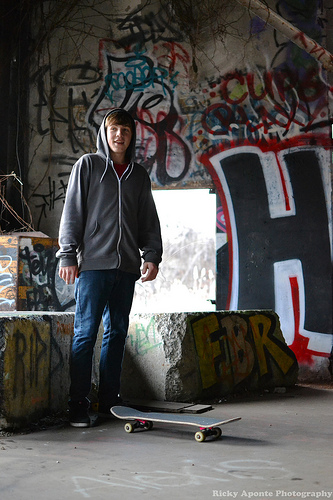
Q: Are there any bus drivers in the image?
A: No, there are no bus drivers.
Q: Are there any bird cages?
A: No, there are no bird cages.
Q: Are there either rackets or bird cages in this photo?
A: No, there are no bird cages or rackets.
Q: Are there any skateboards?
A: Yes, there is a skateboard.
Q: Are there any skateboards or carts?
A: Yes, there is a skateboard.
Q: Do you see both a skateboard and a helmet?
A: No, there is a skateboard but no helmets.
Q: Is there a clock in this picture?
A: No, there are no clocks.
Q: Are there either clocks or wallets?
A: No, there are no clocks or wallets.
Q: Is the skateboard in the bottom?
A: Yes, the skateboard is in the bottom of the image.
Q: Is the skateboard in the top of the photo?
A: No, the skateboard is in the bottom of the image.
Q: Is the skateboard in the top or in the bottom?
A: The skateboard is in the bottom of the image.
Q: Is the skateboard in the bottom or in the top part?
A: The skateboard is in the bottom of the image.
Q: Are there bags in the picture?
A: No, there are no bags.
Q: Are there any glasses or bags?
A: No, there are no bags or glasses.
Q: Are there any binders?
A: No, there are no binders.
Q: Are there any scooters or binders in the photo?
A: No, there are no binders or scooters.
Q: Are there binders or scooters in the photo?
A: No, there are no binders or scooters.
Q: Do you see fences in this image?
A: No, there are no fences.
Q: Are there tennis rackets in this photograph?
A: No, there are no tennis rackets.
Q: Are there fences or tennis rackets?
A: No, there are no tennis rackets or fences.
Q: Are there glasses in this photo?
A: No, there are no glasses.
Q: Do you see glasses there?
A: No, there are no glasses.